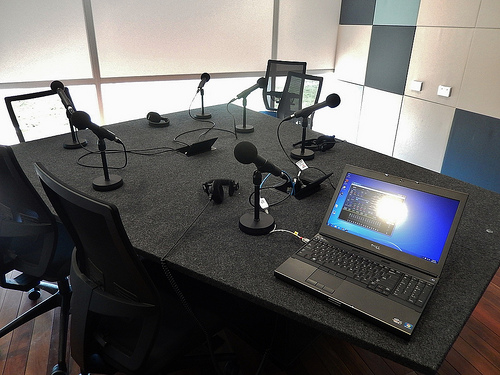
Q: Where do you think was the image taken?
A: It was taken at the office.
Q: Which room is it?
A: It is an office.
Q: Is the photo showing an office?
A: Yes, it is showing an office.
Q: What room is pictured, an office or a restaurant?
A: It is an office.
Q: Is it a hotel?
A: No, it is an office.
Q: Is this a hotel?
A: No, it is an office.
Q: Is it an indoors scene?
A: Yes, it is indoors.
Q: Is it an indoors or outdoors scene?
A: It is indoors.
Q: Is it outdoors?
A: No, it is indoors.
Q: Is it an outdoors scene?
A: No, it is indoors.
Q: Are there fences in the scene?
A: No, there are no fences.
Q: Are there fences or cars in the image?
A: No, there are no fences or cars.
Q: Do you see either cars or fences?
A: No, there are no fences or cars.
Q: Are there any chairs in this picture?
A: Yes, there is a chair.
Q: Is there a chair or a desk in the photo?
A: Yes, there is a chair.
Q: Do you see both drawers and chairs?
A: No, there is a chair but no drawers.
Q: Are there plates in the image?
A: No, there are no plates.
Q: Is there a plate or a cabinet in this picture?
A: No, there are no plates or cabinets.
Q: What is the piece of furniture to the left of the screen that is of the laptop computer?
A: The piece of furniture is a chair.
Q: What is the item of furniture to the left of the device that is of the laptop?
A: The piece of furniture is a chair.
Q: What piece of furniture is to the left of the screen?
A: The piece of furniture is a chair.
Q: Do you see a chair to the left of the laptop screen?
A: Yes, there is a chair to the left of the screen.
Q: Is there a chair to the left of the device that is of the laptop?
A: Yes, there is a chair to the left of the screen.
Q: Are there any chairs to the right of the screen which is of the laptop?
A: No, the chair is to the left of the screen.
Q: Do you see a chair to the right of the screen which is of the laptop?
A: No, the chair is to the left of the screen.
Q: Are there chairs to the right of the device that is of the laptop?
A: No, the chair is to the left of the screen.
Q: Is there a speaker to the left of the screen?
A: No, there is a chair to the left of the screen.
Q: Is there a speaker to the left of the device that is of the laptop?
A: No, there is a chair to the left of the screen.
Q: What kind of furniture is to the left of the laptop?
A: The piece of furniture is a chair.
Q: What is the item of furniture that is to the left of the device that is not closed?
A: The piece of furniture is a chair.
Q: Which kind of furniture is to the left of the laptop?
A: The piece of furniture is a chair.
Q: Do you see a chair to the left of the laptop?
A: Yes, there is a chair to the left of the laptop.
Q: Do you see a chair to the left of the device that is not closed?
A: Yes, there is a chair to the left of the laptop.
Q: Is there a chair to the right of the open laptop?
A: No, the chair is to the left of the laptop.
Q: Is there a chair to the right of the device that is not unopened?
A: No, the chair is to the left of the laptop.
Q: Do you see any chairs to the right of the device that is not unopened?
A: No, the chair is to the left of the laptop.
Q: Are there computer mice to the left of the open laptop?
A: No, there is a chair to the left of the laptop.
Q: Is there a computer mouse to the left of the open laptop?
A: No, there is a chair to the left of the laptop.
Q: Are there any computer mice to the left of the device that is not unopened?
A: No, there is a chair to the left of the laptop.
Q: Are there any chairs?
A: Yes, there is a chair.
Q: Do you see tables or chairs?
A: Yes, there is a chair.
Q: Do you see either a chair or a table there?
A: Yes, there is a chair.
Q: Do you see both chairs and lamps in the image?
A: No, there is a chair but no lamps.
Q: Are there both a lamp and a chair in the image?
A: No, there is a chair but no lamps.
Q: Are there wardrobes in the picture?
A: No, there are no wardrobes.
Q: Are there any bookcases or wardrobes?
A: No, there are no wardrobes or bookcases.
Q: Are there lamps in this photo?
A: No, there are no lamps.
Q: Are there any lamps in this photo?
A: No, there are no lamps.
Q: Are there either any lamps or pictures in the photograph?
A: No, there are no lamps or pictures.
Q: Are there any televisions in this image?
A: No, there are no televisions.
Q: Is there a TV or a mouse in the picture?
A: No, there are no televisions or computer mice.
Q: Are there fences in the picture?
A: No, there are no fences.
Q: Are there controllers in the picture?
A: No, there are no controllers.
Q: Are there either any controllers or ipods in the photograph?
A: No, there are no controllers or ipods.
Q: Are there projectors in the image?
A: No, there are no projectors.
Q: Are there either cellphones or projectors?
A: No, there are no projectors or cellphones.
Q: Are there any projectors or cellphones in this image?
A: No, there are no projectors or cellphones.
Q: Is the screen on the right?
A: Yes, the screen is on the right of the image.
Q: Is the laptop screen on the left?
A: No, the screen is on the right of the image.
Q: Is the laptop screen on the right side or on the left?
A: The screen is on the right of the image.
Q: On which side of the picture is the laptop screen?
A: The screen is on the right of the image.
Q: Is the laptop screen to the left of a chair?
A: No, the screen is to the right of a chair.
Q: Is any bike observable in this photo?
A: No, there are no bikes.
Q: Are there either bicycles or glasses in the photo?
A: No, there are no bicycles or glasses.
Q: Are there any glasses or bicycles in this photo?
A: No, there are no bicycles or glasses.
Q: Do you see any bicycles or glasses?
A: No, there are no bicycles or glasses.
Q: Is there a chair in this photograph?
A: Yes, there is a chair.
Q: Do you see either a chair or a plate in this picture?
A: Yes, there is a chair.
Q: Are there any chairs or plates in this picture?
A: Yes, there is a chair.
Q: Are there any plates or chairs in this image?
A: Yes, there is a chair.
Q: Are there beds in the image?
A: No, there are no beds.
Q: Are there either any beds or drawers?
A: No, there are no beds or drawers.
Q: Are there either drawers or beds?
A: No, there are no beds or drawers.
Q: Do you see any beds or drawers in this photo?
A: No, there are no beds or drawers.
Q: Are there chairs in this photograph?
A: Yes, there is a chair.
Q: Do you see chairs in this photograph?
A: Yes, there is a chair.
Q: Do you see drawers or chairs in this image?
A: Yes, there is a chair.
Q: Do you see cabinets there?
A: No, there are no cabinets.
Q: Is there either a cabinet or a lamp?
A: No, there are no cabinets or lamps.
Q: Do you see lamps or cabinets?
A: No, there are no cabinets or lamps.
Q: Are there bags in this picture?
A: No, there are no bags.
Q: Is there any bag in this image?
A: No, there are no bags.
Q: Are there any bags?
A: No, there are no bags.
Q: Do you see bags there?
A: No, there are no bags.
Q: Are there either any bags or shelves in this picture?
A: No, there are no bags or shelves.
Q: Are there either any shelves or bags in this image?
A: No, there are no bags or shelves.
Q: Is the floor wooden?
A: Yes, the floor is wooden.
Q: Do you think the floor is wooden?
A: Yes, the floor is wooden.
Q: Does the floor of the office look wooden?
A: Yes, the floor is wooden.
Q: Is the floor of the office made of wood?
A: Yes, the floor is made of wood.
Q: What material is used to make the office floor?
A: The floor is made of wood.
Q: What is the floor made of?
A: The floor is made of wood.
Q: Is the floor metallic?
A: No, the floor is wooden.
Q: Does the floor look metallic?
A: No, the floor is wooden.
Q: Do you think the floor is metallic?
A: No, the floor is wooden.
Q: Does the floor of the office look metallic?
A: No, the floor is wooden.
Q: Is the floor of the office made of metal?
A: No, the floor is made of wood.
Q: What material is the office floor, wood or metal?
A: The floor is made of wood.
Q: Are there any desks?
A: Yes, there is a desk.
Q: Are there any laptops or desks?
A: Yes, there is a desk.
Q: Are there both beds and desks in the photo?
A: No, there is a desk but no beds.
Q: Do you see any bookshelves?
A: No, there are no bookshelves.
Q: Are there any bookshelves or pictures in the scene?
A: No, there are no bookshelves or pictures.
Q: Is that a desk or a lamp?
A: That is a desk.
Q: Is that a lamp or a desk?
A: That is a desk.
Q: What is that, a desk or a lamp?
A: That is a desk.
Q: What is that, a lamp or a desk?
A: That is a desk.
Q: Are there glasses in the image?
A: No, there are no glasses.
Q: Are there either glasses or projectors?
A: No, there are no glasses or projectors.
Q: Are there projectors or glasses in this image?
A: No, there are no glasses or projectors.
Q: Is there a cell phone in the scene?
A: No, there are no cell phones.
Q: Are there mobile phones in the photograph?
A: No, there are no mobile phones.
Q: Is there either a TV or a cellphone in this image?
A: No, there are no cell phones or televisions.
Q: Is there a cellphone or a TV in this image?
A: No, there are no cell phones or televisions.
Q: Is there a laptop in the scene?
A: Yes, there is a laptop.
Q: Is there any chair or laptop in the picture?
A: Yes, there is a laptop.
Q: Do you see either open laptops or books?
A: Yes, there is an open laptop.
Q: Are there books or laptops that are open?
A: Yes, the laptop is open.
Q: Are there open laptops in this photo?
A: Yes, there is an open laptop.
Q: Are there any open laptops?
A: Yes, there is an open laptop.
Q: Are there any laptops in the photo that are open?
A: Yes, there is an open laptop.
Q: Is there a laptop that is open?
A: Yes, there is a laptop that is open.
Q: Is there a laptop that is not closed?
A: Yes, there is a open laptop.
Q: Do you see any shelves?
A: No, there are no shelves.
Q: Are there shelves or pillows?
A: No, there are no shelves or pillows.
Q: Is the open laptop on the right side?
A: Yes, the laptop is on the right of the image.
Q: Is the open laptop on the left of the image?
A: No, the laptop computer is on the right of the image.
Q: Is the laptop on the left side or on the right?
A: The laptop is on the right of the image.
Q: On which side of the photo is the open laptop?
A: The laptop is on the right of the image.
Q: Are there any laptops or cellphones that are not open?
A: No, there is a laptop but it is open.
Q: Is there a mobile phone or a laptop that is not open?
A: No, there is a laptop but it is open.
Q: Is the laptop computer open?
A: Yes, the laptop computer is open.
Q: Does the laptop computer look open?
A: Yes, the laptop computer is open.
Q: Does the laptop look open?
A: Yes, the laptop is open.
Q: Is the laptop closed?
A: No, the laptop is open.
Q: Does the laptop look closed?
A: No, the laptop is open.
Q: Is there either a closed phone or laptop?
A: No, there is a laptop but it is open.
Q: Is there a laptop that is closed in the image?
A: No, there is a laptop but it is open.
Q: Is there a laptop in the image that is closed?
A: No, there is a laptop but it is open.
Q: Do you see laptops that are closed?
A: No, there is a laptop but it is open.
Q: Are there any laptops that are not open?
A: No, there is a laptop but it is open.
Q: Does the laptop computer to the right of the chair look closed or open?
A: The laptop is open.